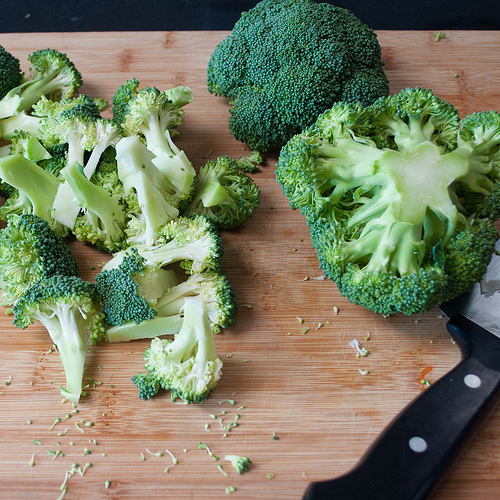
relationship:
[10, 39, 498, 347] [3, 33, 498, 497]
broccoli on board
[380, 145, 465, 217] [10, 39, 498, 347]
stock of broccoli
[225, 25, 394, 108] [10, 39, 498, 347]
head of broccoli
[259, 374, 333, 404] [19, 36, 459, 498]
lines in wood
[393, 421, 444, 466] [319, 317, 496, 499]
circle on handle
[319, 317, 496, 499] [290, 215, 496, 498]
handle of knife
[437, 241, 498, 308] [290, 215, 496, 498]
blade of knife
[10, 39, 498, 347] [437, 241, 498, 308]
broccoli on blade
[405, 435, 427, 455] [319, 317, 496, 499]
circle on handle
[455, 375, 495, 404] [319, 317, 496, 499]
dot on handle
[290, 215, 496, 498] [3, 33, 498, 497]
knife on board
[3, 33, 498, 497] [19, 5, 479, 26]
board on table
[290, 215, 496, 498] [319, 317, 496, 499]
knife with handle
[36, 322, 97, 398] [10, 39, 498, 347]
stem of broccoli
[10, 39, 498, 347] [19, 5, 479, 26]
broccoli on table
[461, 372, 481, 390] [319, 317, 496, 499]
dot holding handle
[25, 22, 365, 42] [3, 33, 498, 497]
edge of board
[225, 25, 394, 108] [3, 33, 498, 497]
head on board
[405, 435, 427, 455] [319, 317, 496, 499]
circle in handle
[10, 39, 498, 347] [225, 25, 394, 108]
broccoli near head